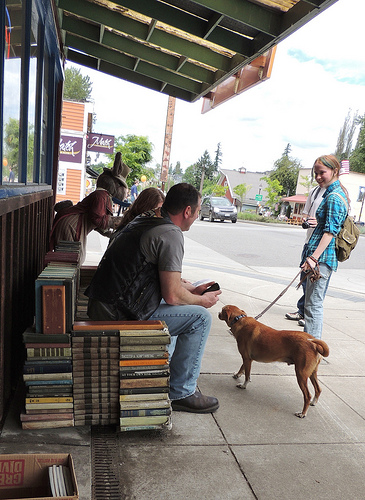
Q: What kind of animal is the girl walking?
A: Dog.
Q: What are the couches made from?
A: Books.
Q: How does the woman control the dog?
A: Leash.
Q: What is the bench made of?
A: Books.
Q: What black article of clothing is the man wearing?
A: Vest.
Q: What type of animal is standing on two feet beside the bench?
A: Rabbit.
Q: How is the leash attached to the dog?
A: Collar.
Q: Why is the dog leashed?
A: Safety.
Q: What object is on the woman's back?
A: Backpack.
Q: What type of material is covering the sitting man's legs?
A: Denim.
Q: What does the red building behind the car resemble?
A: Barn.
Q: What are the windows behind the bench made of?
A: Glass.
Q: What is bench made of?
A: Books.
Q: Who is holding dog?
A: Girl.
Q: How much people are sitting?
A: Two.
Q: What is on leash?
A: Dog.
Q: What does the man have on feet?
A: Shoes.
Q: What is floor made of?
A: Tiles.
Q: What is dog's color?
A: Brown.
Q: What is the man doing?
A: Sitting.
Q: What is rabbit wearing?
A: Hat.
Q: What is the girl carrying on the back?
A: Backpack.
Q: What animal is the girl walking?
A: Dog.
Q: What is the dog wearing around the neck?
A: Collar.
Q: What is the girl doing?
A: Talking to some other people.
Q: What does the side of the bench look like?
A: Stacked books.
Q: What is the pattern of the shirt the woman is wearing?
A: Plaid.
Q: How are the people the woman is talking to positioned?
A: Sitting.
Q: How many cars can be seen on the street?
A: One.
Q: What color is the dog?
A: Brown.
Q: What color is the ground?
A: Gray.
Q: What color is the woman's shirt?
A: Blue.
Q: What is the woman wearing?
A: Backpack.